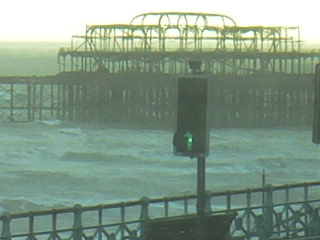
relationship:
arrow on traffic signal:
[180, 127, 197, 157] [171, 72, 210, 158]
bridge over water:
[1, 10, 318, 129] [37, 130, 111, 171]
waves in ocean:
[32, 127, 142, 193] [4, 115, 319, 220]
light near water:
[162, 65, 213, 171] [1, 105, 314, 190]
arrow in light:
[183, 129, 194, 152] [167, 72, 212, 160]